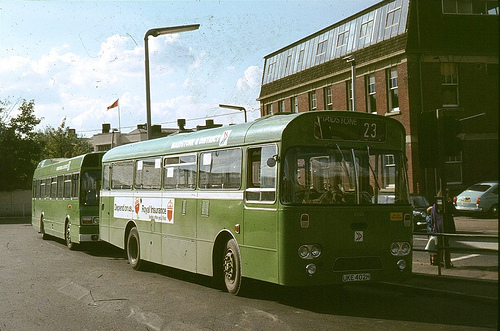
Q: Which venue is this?
A: This is a parking lot.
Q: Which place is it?
A: It is a parking lot.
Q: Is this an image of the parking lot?
A: Yes, it is showing the parking lot.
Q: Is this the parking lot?
A: Yes, it is the parking lot.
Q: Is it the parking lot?
A: Yes, it is the parking lot.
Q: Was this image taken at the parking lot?
A: Yes, it was taken in the parking lot.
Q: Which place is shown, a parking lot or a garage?
A: It is a parking lot.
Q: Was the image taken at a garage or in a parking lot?
A: It was taken at a parking lot.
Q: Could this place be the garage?
A: No, it is the parking lot.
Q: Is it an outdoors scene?
A: Yes, it is outdoors.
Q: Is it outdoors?
A: Yes, it is outdoors.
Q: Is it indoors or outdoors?
A: It is outdoors.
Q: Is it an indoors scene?
A: No, it is outdoors.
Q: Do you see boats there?
A: No, there are no boats.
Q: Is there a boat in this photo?
A: No, there are no boats.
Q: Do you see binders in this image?
A: No, there are no binders.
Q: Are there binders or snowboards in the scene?
A: No, there are no binders or snowboards.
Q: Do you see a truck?
A: No, there are no trucks.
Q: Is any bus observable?
A: Yes, there is a bus.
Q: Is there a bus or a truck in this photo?
A: Yes, there is a bus.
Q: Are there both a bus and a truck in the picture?
A: No, there is a bus but no trucks.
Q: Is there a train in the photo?
A: No, there are no trains.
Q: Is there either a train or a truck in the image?
A: No, there are no trains or trucks.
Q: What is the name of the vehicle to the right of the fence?
A: The vehicle is a bus.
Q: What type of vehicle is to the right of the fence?
A: The vehicle is a bus.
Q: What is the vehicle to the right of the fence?
A: The vehicle is a bus.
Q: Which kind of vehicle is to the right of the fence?
A: The vehicle is a bus.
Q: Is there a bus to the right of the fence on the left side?
A: Yes, there is a bus to the right of the fence.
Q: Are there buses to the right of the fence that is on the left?
A: Yes, there is a bus to the right of the fence.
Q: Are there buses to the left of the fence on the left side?
A: No, the bus is to the right of the fence.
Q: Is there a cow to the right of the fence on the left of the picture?
A: No, there is a bus to the right of the fence.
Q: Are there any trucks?
A: No, there are no trucks.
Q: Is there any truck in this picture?
A: No, there are no trucks.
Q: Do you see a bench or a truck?
A: No, there are no trucks or benches.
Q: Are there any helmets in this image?
A: No, there are no helmets.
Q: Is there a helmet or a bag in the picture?
A: No, there are no helmets or bags.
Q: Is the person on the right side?
A: Yes, the person is on the right of the image.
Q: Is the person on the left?
A: No, the person is on the right of the image.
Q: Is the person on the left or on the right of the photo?
A: The person is on the right of the image.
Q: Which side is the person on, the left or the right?
A: The person is on the right of the image.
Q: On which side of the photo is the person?
A: The person is on the right of the image.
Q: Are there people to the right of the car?
A: Yes, there is a person to the right of the car.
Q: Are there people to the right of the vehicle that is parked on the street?
A: Yes, there is a person to the right of the car.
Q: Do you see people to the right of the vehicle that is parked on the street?
A: Yes, there is a person to the right of the car.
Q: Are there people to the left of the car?
A: No, the person is to the right of the car.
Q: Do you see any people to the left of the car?
A: No, the person is to the right of the car.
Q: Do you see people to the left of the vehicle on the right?
A: No, the person is to the right of the car.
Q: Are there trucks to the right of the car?
A: No, there is a person to the right of the car.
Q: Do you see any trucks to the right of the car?
A: No, there is a person to the right of the car.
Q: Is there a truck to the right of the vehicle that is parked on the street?
A: No, there is a person to the right of the car.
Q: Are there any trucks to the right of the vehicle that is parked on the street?
A: No, there is a person to the right of the car.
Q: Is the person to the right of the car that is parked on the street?
A: Yes, the person is to the right of the car.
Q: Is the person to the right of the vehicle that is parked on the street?
A: Yes, the person is to the right of the car.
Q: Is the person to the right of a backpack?
A: No, the person is to the right of the car.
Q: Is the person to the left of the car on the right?
A: No, the person is to the right of the car.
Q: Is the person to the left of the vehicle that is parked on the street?
A: No, the person is to the right of the car.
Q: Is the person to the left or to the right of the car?
A: The person is to the right of the car.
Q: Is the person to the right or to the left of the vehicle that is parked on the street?
A: The person is to the right of the car.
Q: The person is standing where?
A: The person is standing on the sidewalk.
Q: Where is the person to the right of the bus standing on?
A: The person is standing on the sidewalk.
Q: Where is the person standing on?
A: The person is standing on the sidewalk.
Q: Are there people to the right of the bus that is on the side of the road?
A: Yes, there is a person to the right of the bus.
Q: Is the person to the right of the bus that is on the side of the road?
A: Yes, the person is to the right of the bus.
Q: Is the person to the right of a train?
A: No, the person is to the right of the bus.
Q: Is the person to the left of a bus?
A: No, the person is to the right of a bus.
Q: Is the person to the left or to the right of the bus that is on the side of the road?
A: The person is to the right of the bus.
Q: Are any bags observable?
A: No, there are no bags.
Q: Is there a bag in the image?
A: No, there are no bags.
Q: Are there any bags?
A: No, there are no bags.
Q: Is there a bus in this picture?
A: Yes, there is a bus.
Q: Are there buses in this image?
A: Yes, there is a bus.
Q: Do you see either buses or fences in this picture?
A: Yes, there is a bus.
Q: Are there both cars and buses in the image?
A: Yes, there are both a bus and a car.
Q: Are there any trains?
A: No, there are no trains.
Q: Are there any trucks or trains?
A: No, there are no trains or trucks.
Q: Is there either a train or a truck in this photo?
A: No, there are no trains or trucks.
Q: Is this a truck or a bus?
A: This is a bus.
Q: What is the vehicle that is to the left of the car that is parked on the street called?
A: The vehicle is a bus.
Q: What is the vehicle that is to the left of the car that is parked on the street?
A: The vehicle is a bus.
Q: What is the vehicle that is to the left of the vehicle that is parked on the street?
A: The vehicle is a bus.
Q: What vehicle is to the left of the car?
A: The vehicle is a bus.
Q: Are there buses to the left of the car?
A: Yes, there is a bus to the left of the car.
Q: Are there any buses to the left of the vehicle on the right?
A: Yes, there is a bus to the left of the car.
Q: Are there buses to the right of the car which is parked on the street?
A: No, the bus is to the left of the car.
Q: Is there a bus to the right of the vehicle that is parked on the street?
A: No, the bus is to the left of the car.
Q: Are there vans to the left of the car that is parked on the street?
A: No, there is a bus to the left of the car.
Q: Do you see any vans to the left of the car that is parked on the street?
A: No, there is a bus to the left of the car.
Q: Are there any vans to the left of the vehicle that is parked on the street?
A: No, there is a bus to the left of the car.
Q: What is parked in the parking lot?
A: The bus is parked in the parking lot.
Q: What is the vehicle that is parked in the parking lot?
A: The vehicle is a bus.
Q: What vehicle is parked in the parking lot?
A: The vehicle is a bus.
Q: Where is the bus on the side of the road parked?
A: The bus is parked in the parking lot.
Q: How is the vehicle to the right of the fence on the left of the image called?
A: The vehicle is a bus.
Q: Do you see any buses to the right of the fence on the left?
A: Yes, there is a bus to the right of the fence.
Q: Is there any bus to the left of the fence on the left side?
A: No, the bus is to the right of the fence.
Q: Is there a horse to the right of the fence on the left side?
A: No, there is a bus to the right of the fence.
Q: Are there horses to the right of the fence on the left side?
A: No, there is a bus to the right of the fence.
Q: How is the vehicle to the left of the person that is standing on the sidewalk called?
A: The vehicle is a bus.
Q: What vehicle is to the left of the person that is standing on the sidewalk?
A: The vehicle is a bus.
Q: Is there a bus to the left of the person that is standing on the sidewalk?
A: Yes, there is a bus to the left of the person.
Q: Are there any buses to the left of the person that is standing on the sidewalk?
A: Yes, there is a bus to the left of the person.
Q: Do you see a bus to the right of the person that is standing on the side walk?
A: No, the bus is to the left of the person.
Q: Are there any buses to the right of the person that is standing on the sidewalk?
A: No, the bus is to the left of the person.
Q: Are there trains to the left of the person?
A: No, there is a bus to the left of the person.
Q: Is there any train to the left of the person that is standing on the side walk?
A: No, there is a bus to the left of the person.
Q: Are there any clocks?
A: No, there are no clocks.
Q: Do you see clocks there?
A: No, there are no clocks.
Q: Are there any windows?
A: Yes, there are windows.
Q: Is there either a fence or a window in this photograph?
A: Yes, there are windows.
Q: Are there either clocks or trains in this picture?
A: No, there are no clocks or trains.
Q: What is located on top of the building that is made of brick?
A: The windows are on top of the building.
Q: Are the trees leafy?
A: Yes, the trees are leafy.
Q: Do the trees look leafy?
A: Yes, the trees are leafy.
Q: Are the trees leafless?
A: No, the trees are leafy.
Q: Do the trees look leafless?
A: No, the trees are leafy.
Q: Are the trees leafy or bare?
A: The trees are leafy.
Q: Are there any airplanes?
A: No, there are no airplanes.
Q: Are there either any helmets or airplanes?
A: No, there are no airplanes or helmets.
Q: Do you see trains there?
A: No, there are no trains.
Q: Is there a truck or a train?
A: No, there are no trains or trucks.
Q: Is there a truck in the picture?
A: No, there are no trucks.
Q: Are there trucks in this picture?
A: No, there are no trucks.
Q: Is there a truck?
A: No, there are no trucks.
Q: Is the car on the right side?
A: Yes, the car is on the right of the image.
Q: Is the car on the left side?
A: No, the car is on the right of the image.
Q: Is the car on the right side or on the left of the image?
A: The car is on the right of the image.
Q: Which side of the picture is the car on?
A: The car is on the right of the image.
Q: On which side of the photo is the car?
A: The car is on the right of the image.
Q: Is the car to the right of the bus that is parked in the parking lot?
A: Yes, the car is to the right of the bus.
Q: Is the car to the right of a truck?
A: No, the car is to the right of the bus.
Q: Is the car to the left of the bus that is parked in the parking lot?
A: No, the car is to the right of the bus.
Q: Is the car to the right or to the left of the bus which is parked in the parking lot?
A: The car is to the right of the bus.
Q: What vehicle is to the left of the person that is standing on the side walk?
A: The vehicle is a car.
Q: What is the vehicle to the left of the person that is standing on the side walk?
A: The vehicle is a car.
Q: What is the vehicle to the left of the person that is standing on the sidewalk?
A: The vehicle is a car.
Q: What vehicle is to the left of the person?
A: The vehicle is a car.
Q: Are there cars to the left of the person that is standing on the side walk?
A: Yes, there is a car to the left of the person.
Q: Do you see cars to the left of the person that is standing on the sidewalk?
A: Yes, there is a car to the left of the person.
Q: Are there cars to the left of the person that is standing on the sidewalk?
A: Yes, there is a car to the left of the person.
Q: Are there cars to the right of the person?
A: No, the car is to the left of the person.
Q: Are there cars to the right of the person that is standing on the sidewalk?
A: No, the car is to the left of the person.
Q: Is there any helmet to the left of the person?
A: No, there is a car to the left of the person.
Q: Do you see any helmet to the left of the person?
A: No, there is a car to the left of the person.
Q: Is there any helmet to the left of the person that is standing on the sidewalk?
A: No, there is a car to the left of the person.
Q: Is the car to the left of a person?
A: Yes, the car is to the left of a person.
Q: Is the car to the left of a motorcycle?
A: No, the car is to the left of a person.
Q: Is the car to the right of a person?
A: No, the car is to the left of a person.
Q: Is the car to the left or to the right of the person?
A: The car is to the left of the person.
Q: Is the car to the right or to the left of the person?
A: The car is to the left of the person.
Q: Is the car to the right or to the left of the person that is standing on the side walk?
A: The car is to the left of the person.